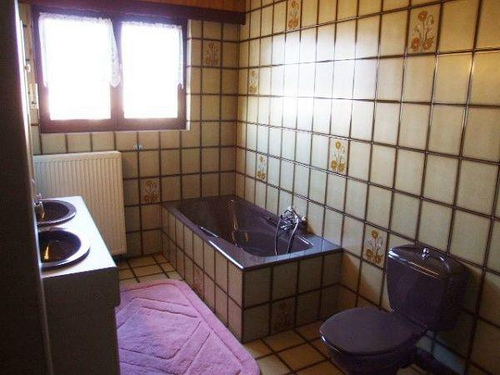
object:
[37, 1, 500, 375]
tiles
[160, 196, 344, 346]
tile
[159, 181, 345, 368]
tub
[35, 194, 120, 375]
sinks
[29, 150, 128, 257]
heater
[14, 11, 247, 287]
wall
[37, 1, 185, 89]
curtains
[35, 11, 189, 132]
windows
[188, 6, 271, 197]
corner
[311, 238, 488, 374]
toilet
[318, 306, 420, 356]
lid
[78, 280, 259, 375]
bathmat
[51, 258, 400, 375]
floor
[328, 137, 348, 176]
tiles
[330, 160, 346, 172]
flowers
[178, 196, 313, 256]
contours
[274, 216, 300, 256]
hose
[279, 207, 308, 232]
faucet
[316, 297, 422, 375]
seat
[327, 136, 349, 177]
print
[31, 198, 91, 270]
double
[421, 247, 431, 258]
flush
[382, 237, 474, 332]
top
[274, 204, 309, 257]
fixtures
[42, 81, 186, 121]
sun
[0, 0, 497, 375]
bathroom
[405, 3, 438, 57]
pattern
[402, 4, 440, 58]
tile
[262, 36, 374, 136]
light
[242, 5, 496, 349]
wall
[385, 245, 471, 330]
back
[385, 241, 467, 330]
tank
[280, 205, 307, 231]
knobs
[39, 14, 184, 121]
light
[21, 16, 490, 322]
walls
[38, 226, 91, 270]
sink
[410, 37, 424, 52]
flower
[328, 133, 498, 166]
grout